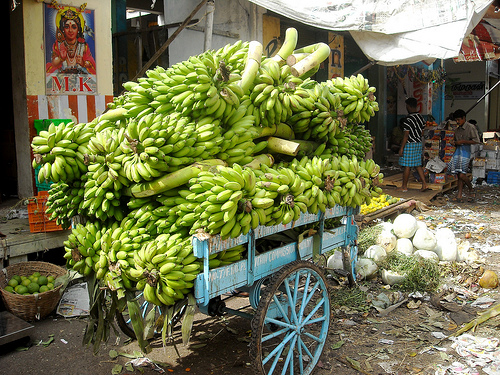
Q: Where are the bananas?
A: In a cart.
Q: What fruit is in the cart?
A: Bananas.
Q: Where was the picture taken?
A: At a market.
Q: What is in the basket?
A: Limes.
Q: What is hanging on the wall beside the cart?
A: A poster.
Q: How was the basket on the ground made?
A: Woven.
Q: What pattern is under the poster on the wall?
A: Stripes.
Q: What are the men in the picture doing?
A: Walking.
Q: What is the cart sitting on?
A: A road.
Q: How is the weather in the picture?
A: Sunny.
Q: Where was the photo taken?
A: Outside somewhere.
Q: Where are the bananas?
A: In a cart.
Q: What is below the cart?
A: Dirt.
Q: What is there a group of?
A: Bananas.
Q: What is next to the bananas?
A: A basket of food.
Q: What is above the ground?
A: Bananas.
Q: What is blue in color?
A: The wheel.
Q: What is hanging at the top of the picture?
A: A white tarp.